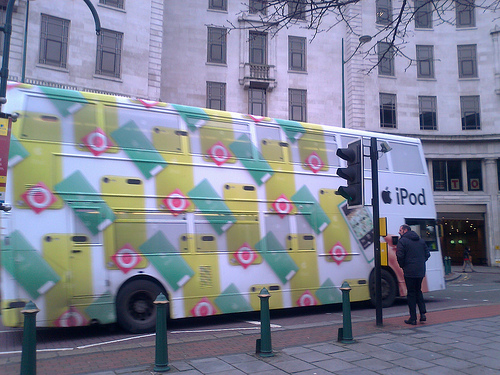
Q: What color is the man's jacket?
A: Blue.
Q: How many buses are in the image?
A: One.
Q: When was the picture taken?
A: Daytime.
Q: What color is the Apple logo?
A: Black.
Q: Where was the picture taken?
A: The sidewalk.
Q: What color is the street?
A: Gray.